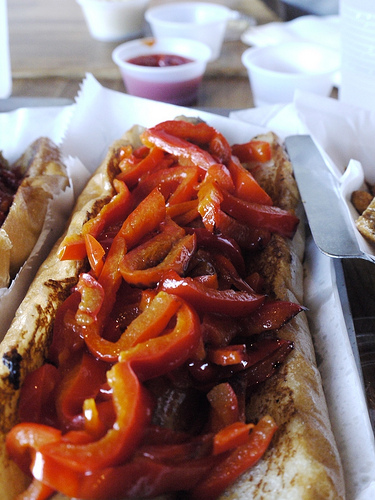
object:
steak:
[0, 150, 23, 236]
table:
[0, 0, 286, 117]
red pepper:
[118, 299, 201, 379]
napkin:
[239, 16, 375, 80]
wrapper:
[55, 69, 270, 161]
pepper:
[206, 382, 240, 426]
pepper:
[94, 187, 166, 334]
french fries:
[353, 195, 375, 243]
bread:
[222, 132, 345, 500]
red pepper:
[158, 270, 266, 317]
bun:
[0, 126, 139, 498]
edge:
[282, 133, 324, 253]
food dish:
[267, 94, 375, 262]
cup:
[110, 34, 212, 105]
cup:
[78, 3, 152, 41]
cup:
[142, 3, 239, 63]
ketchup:
[120, 55, 205, 104]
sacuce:
[151, 380, 200, 428]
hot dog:
[0, 117, 344, 499]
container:
[240, 36, 339, 105]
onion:
[226, 340, 293, 385]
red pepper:
[118, 235, 194, 286]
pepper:
[212, 422, 254, 456]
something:
[172, 0, 207, 27]